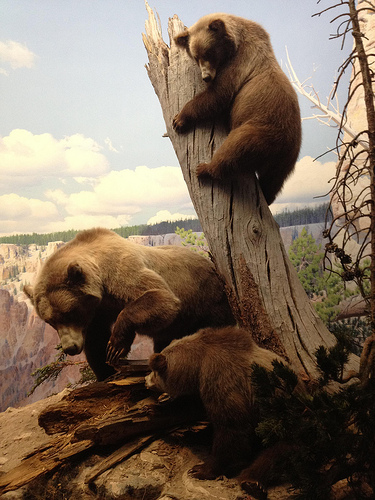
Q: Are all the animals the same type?
A: Yes, all the animals are bears.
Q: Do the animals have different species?
A: No, all the animals are bears.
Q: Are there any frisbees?
A: No, there are no frisbees.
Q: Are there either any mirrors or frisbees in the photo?
A: No, there are no frisbees or mirrors.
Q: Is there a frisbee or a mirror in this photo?
A: No, there are no frisbees or mirrors.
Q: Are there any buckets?
A: No, there are no buckets.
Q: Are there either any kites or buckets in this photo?
A: No, there are no buckets or kites.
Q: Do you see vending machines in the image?
A: No, there are no vending machines.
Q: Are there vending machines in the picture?
A: No, there are no vending machines.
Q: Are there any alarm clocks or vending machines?
A: No, there are no vending machines or alarm clocks.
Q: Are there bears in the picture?
A: Yes, there is a bear.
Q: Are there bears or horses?
A: Yes, there is a bear.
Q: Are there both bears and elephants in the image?
A: No, there is a bear but no elephants.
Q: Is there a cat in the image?
A: No, there are no cats.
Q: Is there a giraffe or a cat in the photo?
A: No, there are no cats or giraffes.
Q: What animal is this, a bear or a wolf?
A: This is a bear.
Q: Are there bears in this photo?
A: Yes, there are bears.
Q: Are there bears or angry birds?
A: Yes, there are bears.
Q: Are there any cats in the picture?
A: No, there are no cats.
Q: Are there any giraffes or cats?
A: No, there are no cats or giraffes.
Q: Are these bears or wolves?
A: These are bears.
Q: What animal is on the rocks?
A: The bears are on the rocks.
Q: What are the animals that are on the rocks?
A: The animals are bears.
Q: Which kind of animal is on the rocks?
A: The animals are bears.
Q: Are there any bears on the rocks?
A: Yes, there are bears on the rocks.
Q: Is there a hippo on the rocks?
A: No, there are bears on the rocks.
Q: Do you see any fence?
A: No, there are no fences.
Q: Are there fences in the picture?
A: No, there are no fences.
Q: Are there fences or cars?
A: No, there are no fences or cars.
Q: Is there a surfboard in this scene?
A: No, there are no surfboards.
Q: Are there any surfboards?
A: No, there are no surfboards.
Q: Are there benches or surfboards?
A: No, there are no surfboards or benches.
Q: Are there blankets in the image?
A: No, there are no blankets.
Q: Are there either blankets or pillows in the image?
A: No, there are no blankets or pillows.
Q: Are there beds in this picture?
A: No, there are no beds.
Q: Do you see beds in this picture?
A: No, there are no beds.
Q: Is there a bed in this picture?
A: No, there are no beds.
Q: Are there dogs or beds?
A: No, there are no beds or dogs.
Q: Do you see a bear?
A: Yes, there is a bear.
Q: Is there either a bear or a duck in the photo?
A: Yes, there is a bear.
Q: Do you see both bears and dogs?
A: No, there is a bear but no dogs.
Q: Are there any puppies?
A: No, there are no puppies.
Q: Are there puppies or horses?
A: No, there are no puppies or horses.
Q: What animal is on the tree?
A: The bear is on the tree.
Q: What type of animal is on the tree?
A: The animal is a bear.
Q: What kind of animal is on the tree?
A: The animal is a bear.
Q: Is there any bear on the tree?
A: Yes, there is a bear on the tree.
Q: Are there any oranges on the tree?
A: No, there is a bear on the tree.